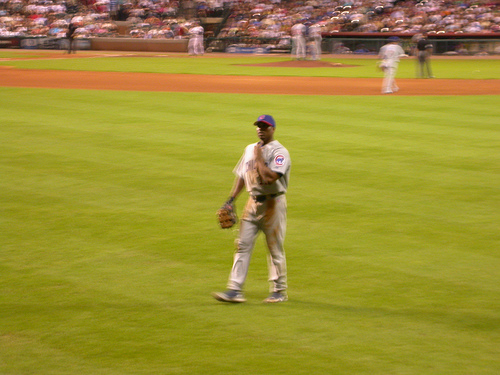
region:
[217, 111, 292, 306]
a baseball player on a baseball field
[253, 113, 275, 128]
man wearing a blue and red baseball cap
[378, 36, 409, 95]
a baseball player walking on a baseball field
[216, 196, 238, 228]
man wearing a leathr catcher's mitt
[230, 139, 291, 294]
man wearing a white stripe uniform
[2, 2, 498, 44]
spectators watching a baseball game in the bleachers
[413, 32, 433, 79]
an umpire wearing black and gray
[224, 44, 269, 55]
an advertisement on a baseball field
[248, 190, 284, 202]
man wearing a black belt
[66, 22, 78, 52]
man wearing black sanding on a baseball field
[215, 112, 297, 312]
Baseball player in position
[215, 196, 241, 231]
Baseball gloves in one hand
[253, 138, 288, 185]
Arm up leaning against chest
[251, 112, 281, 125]
Blue and red player's hat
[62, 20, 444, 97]
Game players out in field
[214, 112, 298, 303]
Baseball player ready for the game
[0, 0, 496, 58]
Crowd of people cheering for the game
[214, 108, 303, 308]
Baseball player in white shirt and shoes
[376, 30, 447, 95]
Group of two players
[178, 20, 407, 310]
Set of five players in white jerseys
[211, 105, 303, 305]
Professional basesball player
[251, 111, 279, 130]
baseball players blue & red hat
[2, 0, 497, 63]
grandstand filled with baseball fans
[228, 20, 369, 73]
two players standing on pitchers mound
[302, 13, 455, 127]
baseball player walking towards home plate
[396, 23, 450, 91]
baseball umpire dressed in black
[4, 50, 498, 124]
baseball fields dirt baseline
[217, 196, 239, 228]
BROWN LEATHER BASEBALL MITT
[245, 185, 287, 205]
black leather belt with silver buckle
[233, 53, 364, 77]
dirt pitching mound in green infield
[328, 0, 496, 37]
part of the public out of focus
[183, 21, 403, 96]
four out of focus baseball players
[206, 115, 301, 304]
the baseball player ready to play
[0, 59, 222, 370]
part of the baseball field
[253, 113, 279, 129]
a blue cap with red line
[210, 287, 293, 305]
a pair of sneakers out of focus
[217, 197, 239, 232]
the brown player glove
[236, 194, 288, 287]
the baseball player dirty pants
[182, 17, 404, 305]
five baseball players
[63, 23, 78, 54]
a man in black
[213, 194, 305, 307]
dirty baseball white pants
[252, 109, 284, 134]
blue and red baseball cap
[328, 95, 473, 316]
green field of grass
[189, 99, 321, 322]
man playing a baseball game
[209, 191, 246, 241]
brown baseball glove on hand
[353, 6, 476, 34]
blurry audience in the distance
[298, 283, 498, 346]
black shadow in the grass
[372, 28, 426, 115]
man walking on baseball field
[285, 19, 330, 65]
blurry image on two people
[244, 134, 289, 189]
harm touching the chest